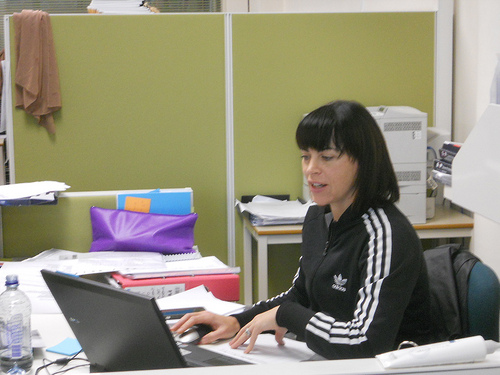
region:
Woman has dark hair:
[298, 99, 400, 217]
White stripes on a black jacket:
[304, 205, 393, 347]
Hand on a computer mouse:
[364, 99, 431, 241]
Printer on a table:
[298, 104, 430, 243]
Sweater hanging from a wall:
[7, 6, 64, 138]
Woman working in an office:
[10, 3, 490, 369]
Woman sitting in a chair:
[281, 95, 496, 348]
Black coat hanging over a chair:
[420, 235, 497, 338]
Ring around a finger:
[238, 317, 258, 344]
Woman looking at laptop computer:
[39, 97, 446, 363]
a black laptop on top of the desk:
[40, 268, 256, 372]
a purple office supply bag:
[88, 205, 198, 251]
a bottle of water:
[0, 274, 33, 374]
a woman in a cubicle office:
[1, 1, 498, 373]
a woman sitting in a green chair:
[170, 98, 498, 361]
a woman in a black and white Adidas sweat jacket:
[170, 98, 432, 361]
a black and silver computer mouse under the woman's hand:
[171, 312, 228, 344]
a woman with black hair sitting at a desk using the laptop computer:
[39, 99, 433, 371]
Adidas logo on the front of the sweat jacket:
[331, 274, 348, 292]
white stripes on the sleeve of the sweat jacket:
[305, 209, 395, 346]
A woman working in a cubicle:
[42, 59, 497, 374]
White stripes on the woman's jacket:
[355, 210, 420, 348]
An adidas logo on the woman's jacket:
[322, 269, 354, 294]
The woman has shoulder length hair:
[286, 95, 411, 210]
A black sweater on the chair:
[416, 235, 491, 338]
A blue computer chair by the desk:
[464, 265, 499, 343]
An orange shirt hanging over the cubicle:
[13, 9, 76, 131]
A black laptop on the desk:
[42, 266, 187, 370]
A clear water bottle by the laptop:
[0, 280, 56, 372]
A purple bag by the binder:
[88, 205, 199, 260]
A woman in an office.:
[2, 5, 494, 374]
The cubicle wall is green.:
[2, 15, 433, 260]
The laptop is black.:
[37, 265, 265, 372]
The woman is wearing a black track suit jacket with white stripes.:
[230, 205, 431, 374]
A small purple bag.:
[85, 205, 196, 255]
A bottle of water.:
[1, 268, 36, 373]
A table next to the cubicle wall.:
[228, 191, 470, 307]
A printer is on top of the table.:
[295, 100, 428, 225]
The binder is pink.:
[106, 270, 242, 301]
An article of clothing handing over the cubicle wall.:
[4, 7, 67, 145]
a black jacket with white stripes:
[232, 202, 436, 363]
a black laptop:
[37, 267, 255, 368]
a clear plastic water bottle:
[2, 272, 34, 374]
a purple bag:
[85, 204, 196, 258]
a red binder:
[109, 269, 243, 302]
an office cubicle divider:
[4, 8, 232, 269]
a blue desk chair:
[461, 258, 498, 346]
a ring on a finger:
[242, 324, 251, 339]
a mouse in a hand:
[169, 325, 213, 346]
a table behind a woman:
[238, 207, 474, 326]